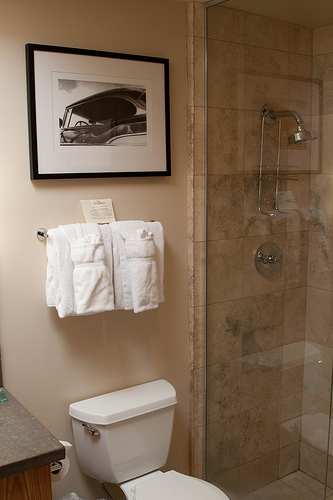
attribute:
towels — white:
[38, 222, 169, 316]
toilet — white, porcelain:
[63, 377, 234, 500]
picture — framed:
[21, 40, 174, 182]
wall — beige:
[1, 1, 187, 500]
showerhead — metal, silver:
[261, 105, 318, 150]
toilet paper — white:
[48, 455, 75, 484]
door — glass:
[205, 2, 332, 499]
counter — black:
[0, 381, 66, 477]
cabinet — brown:
[0, 464, 53, 499]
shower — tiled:
[191, 1, 332, 499]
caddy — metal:
[253, 110, 292, 223]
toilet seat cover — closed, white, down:
[118, 467, 231, 499]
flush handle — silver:
[78, 421, 101, 442]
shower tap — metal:
[250, 238, 286, 280]